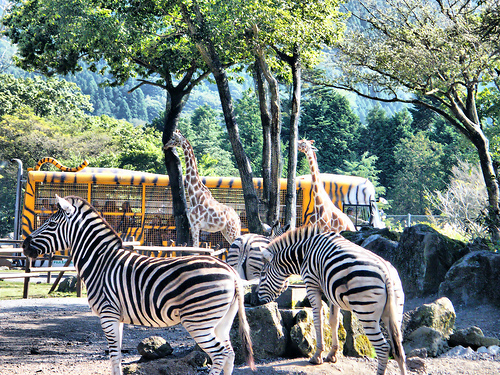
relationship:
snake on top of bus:
[24, 156, 93, 170] [23, 166, 377, 262]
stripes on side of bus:
[86, 172, 148, 188] [23, 166, 377, 262]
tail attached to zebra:
[219, 284, 259, 367] [8, 207, 236, 370]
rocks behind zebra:
[240, 303, 299, 354] [8, 207, 236, 370]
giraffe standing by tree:
[300, 115, 365, 240] [227, 6, 286, 192]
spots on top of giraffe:
[313, 215, 347, 229] [300, 115, 365, 240]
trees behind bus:
[60, 122, 155, 163] [195, 174, 378, 217]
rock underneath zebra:
[134, 333, 172, 359] [8, 207, 236, 370]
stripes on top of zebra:
[113, 284, 188, 314] [8, 207, 236, 370]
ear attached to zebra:
[55, 195, 77, 219] [8, 207, 236, 370]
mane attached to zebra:
[84, 206, 133, 240] [8, 207, 236, 370]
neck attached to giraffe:
[304, 155, 336, 197] [300, 115, 365, 240]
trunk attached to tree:
[173, 243, 194, 252] [227, 6, 286, 192]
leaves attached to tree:
[18, 46, 107, 86] [227, 6, 286, 192]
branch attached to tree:
[134, 77, 177, 91] [227, 6, 286, 192]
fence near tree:
[29, 260, 88, 295] [227, 6, 286, 192]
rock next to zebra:
[134, 333, 172, 359] [8, 207, 236, 370]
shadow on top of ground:
[3, 325, 75, 362] [416, 362, 480, 372]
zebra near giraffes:
[22, 193, 235, 371] [165, 132, 367, 232]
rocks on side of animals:
[240, 303, 299, 354] [210, 197, 368, 285]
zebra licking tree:
[8, 207, 236, 370] [227, 6, 286, 192]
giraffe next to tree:
[300, 115, 365, 240] [227, 6, 286, 192]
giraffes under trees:
[165, 132, 367, 232] [60, 122, 155, 163]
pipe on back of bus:
[0, 231, 21, 244] [195, 174, 378, 217]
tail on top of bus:
[219, 284, 259, 367] [195, 174, 378, 217]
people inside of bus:
[74, 190, 159, 216] [195, 174, 378, 217]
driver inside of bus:
[343, 207, 370, 224] [195, 174, 378, 217]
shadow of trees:
[0, 301, 212, 374] [60, 122, 155, 163]